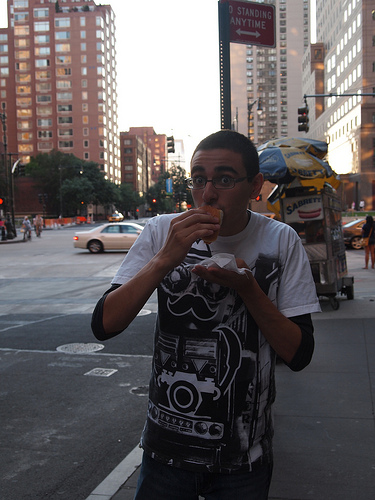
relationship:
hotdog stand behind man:
[276, 180, 355, 309] [91, 130, 322, 499]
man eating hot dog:
[91, 130, 322, 499] [195, 201, 224, 245]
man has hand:
[91, 130, 322, 499] [187, 257, 255, 291]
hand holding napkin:
[187, 257, 255, 291] [185, 250, 251, 274]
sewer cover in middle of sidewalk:
[57, 338, 105, 359] [0, 221, 375, 500]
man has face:
[91, 130, 322, 499] [187, 149, 246, 230]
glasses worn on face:
[181, 171, 256, 191] [187, 149, 246, 230]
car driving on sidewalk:
[72, 220, 148, 256] [0, 221, 375, 500]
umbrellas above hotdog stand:
[255, 133, 339, 215] [276, 180, 355, 309]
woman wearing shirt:
[356, 215, 374, 275] [360, 219, 374, 245]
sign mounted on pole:
[228, 0, 277, 50] [215, 1, 234, 132]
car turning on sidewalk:
[72, 220, 148, 256] [0, 221, 375, 500]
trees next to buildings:
[13, 151, 193, 220] [1, 1, 167, 229]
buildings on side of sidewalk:
[1, 1, 167, 229] [0, 221, 375, 500]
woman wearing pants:
[356, 215, 374, 275] [361, 242, 374, 271]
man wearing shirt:
[91, 130, 322, 499] [109, 209, 320, 474]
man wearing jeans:
[91, 130, 322, 499] [133, 449, 273, 499]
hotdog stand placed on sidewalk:
[276, 180, 355, 309] [113, 249, 374, 499]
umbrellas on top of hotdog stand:
[255, 133, 339, 215] [276, 180, 355, 309]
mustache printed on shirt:
[163, 291, 219, 322] [109, 209, 320, 474]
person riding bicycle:
[20, 214, 34, 235] [19, 228, 33, 240]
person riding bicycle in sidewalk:
[20, 214, 34, 235] [0, 221, 375, 500]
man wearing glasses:
[91, 130, 322, 499] [181, 171, 256, 191]